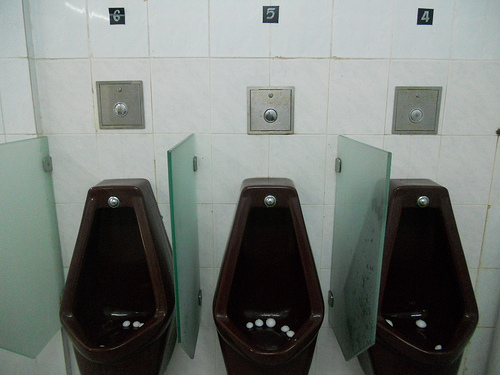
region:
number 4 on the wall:
[414, 3, 442, 33]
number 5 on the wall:
[254, 0, 291, 30]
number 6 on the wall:
[103, 5, 133, 22]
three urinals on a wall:
[47, 136, 484, 373]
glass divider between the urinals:
[321, 130, 390, 362]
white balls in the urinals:
[239, 312, 295, 342]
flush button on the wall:
[233, 73, 301, 145]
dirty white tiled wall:
[314, 29, 390, 121]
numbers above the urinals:
[91, 3, 454, 38]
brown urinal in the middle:
[209, 169, 357, 368]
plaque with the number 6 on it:
[106, 6, 126, 23]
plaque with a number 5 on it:
[261, 3, 278, 23]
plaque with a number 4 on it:
[416, 5, 435, 25]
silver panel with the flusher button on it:
[93, 78, 145, 131]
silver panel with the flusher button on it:
[244, 84, 296, 136]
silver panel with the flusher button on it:
[391, 83, 442, 136]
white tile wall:
[1, 0, 498, 374]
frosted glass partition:
[328, 132, 394, 362]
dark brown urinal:
[210, 175, 327, 373]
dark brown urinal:
[59, 175, 179, 372]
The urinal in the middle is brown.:
[211, 168, 318, 366]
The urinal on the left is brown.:
[55, 183, 175, 371]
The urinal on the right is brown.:
[378, 178, 482, 373]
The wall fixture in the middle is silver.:
[240, 79, 301, 139]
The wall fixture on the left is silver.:
[91, 77, 151, 132]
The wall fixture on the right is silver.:
[384, 83, 444, 138]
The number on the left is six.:
[105, 5, 127, 25]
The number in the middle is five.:
[256, 0, 263, 26]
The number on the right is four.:
[413, 3, 434, 26]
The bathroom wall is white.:
[165, 12, 232, 80]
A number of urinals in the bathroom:
[24, 36, 494, 371]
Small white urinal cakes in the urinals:
[247, 316, 292, 336]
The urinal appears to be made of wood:
[208, 160, 343, 368]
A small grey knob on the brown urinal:
[262, 192, 282, 209]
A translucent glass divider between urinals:
[327, 132, 390, 347]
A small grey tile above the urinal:
[387, 79, 455, 136]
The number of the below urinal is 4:
[413, 3, 439, 34]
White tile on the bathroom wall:
[171, 37, 403, 77]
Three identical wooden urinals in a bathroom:
[51, 165, 488, 361]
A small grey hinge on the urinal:
[333, 157, 349, 177]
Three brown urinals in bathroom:
[28, 161, 489, 369]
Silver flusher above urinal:
[244, 86, 301, 140]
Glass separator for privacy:
[153, 135, 215, 357]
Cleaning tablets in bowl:
[242, 315, 304, 336]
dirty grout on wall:
[146, 50, 401, 66]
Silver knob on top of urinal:
[79, 192, 130, 214]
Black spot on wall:
[482, 124, 499, 137]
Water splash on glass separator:
[357, 223, 377, 348]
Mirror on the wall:
[7, 18, 41, 119]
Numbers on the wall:
[91, 1, 446, 37]